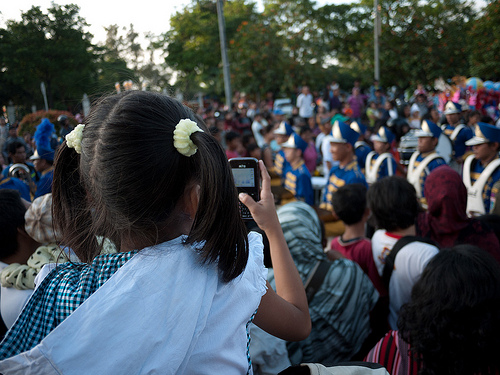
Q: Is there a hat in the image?
A: Yes, there is a hat.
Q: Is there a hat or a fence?
A: Yes, there is a hat.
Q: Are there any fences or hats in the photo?
A: Yes, there is a hat.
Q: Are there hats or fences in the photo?
A: Yes, there is a hat.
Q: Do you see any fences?
A: No, there are no fences.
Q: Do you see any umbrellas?
A: No, there are no umbrellas.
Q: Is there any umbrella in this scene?
A: No, there are no umbrellas.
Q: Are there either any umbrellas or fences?
A: No, there are no umbrellas or fences.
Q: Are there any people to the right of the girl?
A: Yes, there are people to the right of the girl.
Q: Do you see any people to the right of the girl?
A: Yes, there are people to the right of the girl.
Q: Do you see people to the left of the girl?
A: No, the people are to the right of the girl.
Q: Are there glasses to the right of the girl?
A: No, there are people to the right of the girl.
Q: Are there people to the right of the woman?
A: Yes, there are people to the right of the woman.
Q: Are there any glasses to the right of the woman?
A: No, there are people to the right of the woman.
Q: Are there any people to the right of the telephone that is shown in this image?
A: Yes, there are people to the right of the telephone.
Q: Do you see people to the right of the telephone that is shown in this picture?
A: Yes, there are people to the right of the telephone.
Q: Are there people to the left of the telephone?
A: No, the people are to the right of the telephone.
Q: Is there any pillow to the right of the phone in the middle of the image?
A: No, there are people to the right of the telephone.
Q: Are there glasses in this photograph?
A: No, there are no glasses.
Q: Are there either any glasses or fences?
A: No, there are no glasses or fences.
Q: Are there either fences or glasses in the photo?
A: No, there are no glasses or fences.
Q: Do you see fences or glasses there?
A: No, there are no glasses or fences.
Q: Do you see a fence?
A: No, there are no fences.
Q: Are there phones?
A: Yes, there is a phone.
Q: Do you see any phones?
A: Yes, there is a phone.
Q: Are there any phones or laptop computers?
A: Yes, there is a phone.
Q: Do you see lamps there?
A: No, there are no lamps.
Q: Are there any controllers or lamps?
A: No, there are no lamps or controllers.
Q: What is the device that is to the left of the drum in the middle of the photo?
A: The device is a phone.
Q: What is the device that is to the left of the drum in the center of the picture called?
A: The device is a phone.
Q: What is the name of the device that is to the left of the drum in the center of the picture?
A: The device is a phone.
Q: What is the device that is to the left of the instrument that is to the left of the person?
A: The device is a phone.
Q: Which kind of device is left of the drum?
A: The device is a phone.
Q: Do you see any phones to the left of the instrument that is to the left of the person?
A: Yes, there is a phone to the left of the drum.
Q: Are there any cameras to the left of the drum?
A: No, there is a phone to the left of the drum.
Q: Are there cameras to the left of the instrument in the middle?
A: No, there is a phone to the left of the drum.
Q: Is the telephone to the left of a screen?
A: No, the telephone is to the left of the drum.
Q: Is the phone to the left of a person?
A: Yes, the phone is to the left of a person.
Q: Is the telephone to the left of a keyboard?
A: No, the telephone is to the left of a person.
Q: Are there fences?
A: No, there are no fences.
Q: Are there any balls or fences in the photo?
A: No, there are no fences or balls.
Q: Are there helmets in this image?
A: No, there are no helmets.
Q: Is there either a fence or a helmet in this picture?
A: No, there are no helmets or fences.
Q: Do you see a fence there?
A: No, there are no fences.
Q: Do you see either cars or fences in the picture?
A: No, there are no fences or cars.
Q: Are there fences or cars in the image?
A: No, there are no fences or cars.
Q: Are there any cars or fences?
A: No, there are no fences or cars.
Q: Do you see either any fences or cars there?
A: No, there are no fences or cars.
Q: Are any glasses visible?
A: No, there are no glasses.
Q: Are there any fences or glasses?
A: No, there are no glasses or fences.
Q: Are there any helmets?
A: No, there are no helmets.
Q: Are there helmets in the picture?
A: No, there are no helmets.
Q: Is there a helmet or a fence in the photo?
A: No, there are no helmets or fences.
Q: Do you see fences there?
A: No, there are no fences.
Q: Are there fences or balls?
A: No, there are no fences or balls.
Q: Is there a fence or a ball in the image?
A: No, there are no fences or balls.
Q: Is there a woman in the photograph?
A: Yes, there is a woman.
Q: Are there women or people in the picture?
A: Yes, there is a woman.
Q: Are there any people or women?
A: Yes, there is a woman.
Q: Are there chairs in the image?
A: No, there are no chairs.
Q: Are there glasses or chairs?
A: No, there are no chairs or glasses.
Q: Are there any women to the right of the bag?
A: No, the woman is to the left of the bag.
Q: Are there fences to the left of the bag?
A: No, there is a woman to the left of the bag.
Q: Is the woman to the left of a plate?
A: No, the woman is to the left of the bag.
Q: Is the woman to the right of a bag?
A: No, the woman is to the left of a bag.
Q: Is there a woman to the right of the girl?
A: Yes, there is a woman to the right of the girl.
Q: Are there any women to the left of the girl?
A: No, the woman is to the right of the girl.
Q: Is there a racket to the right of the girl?
A: No, there is a woman to the right of the girl.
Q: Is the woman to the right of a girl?
A: Yes, the woman is to the right of a girl.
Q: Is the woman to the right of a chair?
A: No, the woman is to the right of a girl.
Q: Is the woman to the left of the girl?
A: No, the woman is to the right of the girl.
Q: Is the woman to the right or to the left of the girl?
A: The woman is to the right of the girl.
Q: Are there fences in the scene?
A: No, there are no fences.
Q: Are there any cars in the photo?
A: No, there are no cars.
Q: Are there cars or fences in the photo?
A: No, there are no cars or fences.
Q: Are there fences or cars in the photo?
A: No, there are no cars or fences.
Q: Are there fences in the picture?
A: No, there are no fences.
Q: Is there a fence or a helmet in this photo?
A: No, there are no fences or helmets.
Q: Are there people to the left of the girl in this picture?
A: No, the person is to the right of the girl.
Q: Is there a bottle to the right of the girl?
A: No, there is a person to the right of the girl.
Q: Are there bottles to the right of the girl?
A: No, there is a person to the right of the girl.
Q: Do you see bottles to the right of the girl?
A: No, there is a person to the right of the girl.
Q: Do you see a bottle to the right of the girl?
A: No, there is a person to the right of the girl.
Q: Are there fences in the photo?
A: No, there are no fences.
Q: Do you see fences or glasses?
A: No, there are no fences or glasses.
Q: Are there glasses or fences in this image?
A: No, there are no fences or glasses.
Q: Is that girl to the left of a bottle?
A: No, the girl is to the left of a person.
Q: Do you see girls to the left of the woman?
A: Yes, there is a girl to the left of the woman.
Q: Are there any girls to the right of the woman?
A: No, the girl is to the left of the woman.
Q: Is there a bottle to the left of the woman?
A: No, there is a girl to the left of the woman.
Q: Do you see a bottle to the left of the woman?
A: No, there is a girl to the left of the woman.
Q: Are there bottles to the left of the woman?
A: No, there is a girl to the left of the woman.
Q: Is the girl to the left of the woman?
A: Yes, the girl is to the left of the woman.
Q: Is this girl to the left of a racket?
A: No, the girl is to the left of the woman.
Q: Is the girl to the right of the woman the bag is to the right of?
A: No, the girl is to the left of the woman.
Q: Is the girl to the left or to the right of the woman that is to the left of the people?
A: The girl is to the left of the woman.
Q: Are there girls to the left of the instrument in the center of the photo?
A: Yes, there is a girl to the left of the drum.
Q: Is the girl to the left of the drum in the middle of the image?
A: Yes, the girl is to the left of the drum.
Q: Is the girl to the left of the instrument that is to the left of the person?
A: Yes, the girl is to the left of the drum.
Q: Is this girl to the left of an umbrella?
A: No, the girl is to the left of the drum.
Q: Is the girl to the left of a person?
A: Yes, the girl is to the left of a person.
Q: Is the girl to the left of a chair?
A: No, the girl is to the left of a person.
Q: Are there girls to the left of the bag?
A: Yes, there is a girl to the left of the bag.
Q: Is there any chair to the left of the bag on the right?
A: No, there is a girl to the left of the bag.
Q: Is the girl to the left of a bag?
A: Yes, the girl is to the left of a bag.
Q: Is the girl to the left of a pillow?
A: No, the girl is to the left of a bag.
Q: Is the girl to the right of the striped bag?
A: No, the girl is to the left of the bag.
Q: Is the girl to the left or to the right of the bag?
A: The girl is to the left of the bag.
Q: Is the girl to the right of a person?
A: No, the girl is to the left of a person.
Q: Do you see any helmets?
A: No, there are no helmets.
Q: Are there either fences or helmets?
A: No, there are no helmets or fences.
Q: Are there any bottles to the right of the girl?
A: No, there is a person to the right of the girl.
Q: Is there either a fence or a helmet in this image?
A: No, there are no fences or helmets.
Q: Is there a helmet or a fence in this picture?
A: No, there are no fences or helmets.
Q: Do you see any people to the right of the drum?
A: Yes, there is a person to the right of the drum.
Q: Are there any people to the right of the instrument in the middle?
A: Yes, there is a person to the right of the drum.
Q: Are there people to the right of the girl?
A: Yes, there is a person to the right of the girl.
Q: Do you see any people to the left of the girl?
A: No, the person is to the right of the girl.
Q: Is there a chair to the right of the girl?
A: No, there is a person to the right of the girl.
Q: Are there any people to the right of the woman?
A: Yes, there is a person to the right of the woman.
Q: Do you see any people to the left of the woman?
A: No, the person is to the right of the woman.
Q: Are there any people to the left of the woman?
A: No, the person is to the right of the woman.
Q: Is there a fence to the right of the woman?
A: No, there is a person to the right of the woman.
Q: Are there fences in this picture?
A: No, there are no fences.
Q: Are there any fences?
A: No, there are no fences.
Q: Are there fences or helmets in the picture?
A: No, there are no fences or helmets.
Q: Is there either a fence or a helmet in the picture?
A: No, there are no fences or helmets.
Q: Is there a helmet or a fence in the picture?
A: No, there are no fences or helmets.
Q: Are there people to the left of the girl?
A: No, the person is to the right of the girl.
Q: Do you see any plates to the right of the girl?
A: No, there is a person to the right of the girl.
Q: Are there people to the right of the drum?
A: Yes, there is a person to the right of the drum.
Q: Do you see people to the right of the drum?
A: Yes, there is a person to the right of the drum.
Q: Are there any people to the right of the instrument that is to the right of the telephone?
A: Yes, there is a person to the right of the drum.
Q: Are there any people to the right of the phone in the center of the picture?
A: Yes, there is a person to the right of the phone.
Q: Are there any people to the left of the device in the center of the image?
A: No, the person is to the right of the phone.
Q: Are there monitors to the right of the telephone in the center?
A: No, there is a person to the right of the phone.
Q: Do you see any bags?
A: Yes, there is a bag.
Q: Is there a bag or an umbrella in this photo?
A: Yes, there is a bag.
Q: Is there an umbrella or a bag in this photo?
A: Yes, there is a bag.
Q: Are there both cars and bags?
A: No, there is a bag but no cars.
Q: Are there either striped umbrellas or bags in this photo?
A: Yes, there is a striped bag.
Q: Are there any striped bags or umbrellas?
A: Yes, there is a striped bag.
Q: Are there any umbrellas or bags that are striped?
A: Yes, the bag is striped.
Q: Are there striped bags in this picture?
A: Yes, there is a striped bag.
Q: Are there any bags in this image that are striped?
A: Yes, there is a bag that is striped.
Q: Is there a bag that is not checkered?
A: Yes, there is a striped bag.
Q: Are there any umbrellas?
A: No, there are no umbrellas.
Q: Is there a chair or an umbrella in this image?
A: No, there are no umbrellas or chairs.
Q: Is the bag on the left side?
A: No, the bag is on the right of the image.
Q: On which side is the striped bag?
A: The bag is on the right of the image.